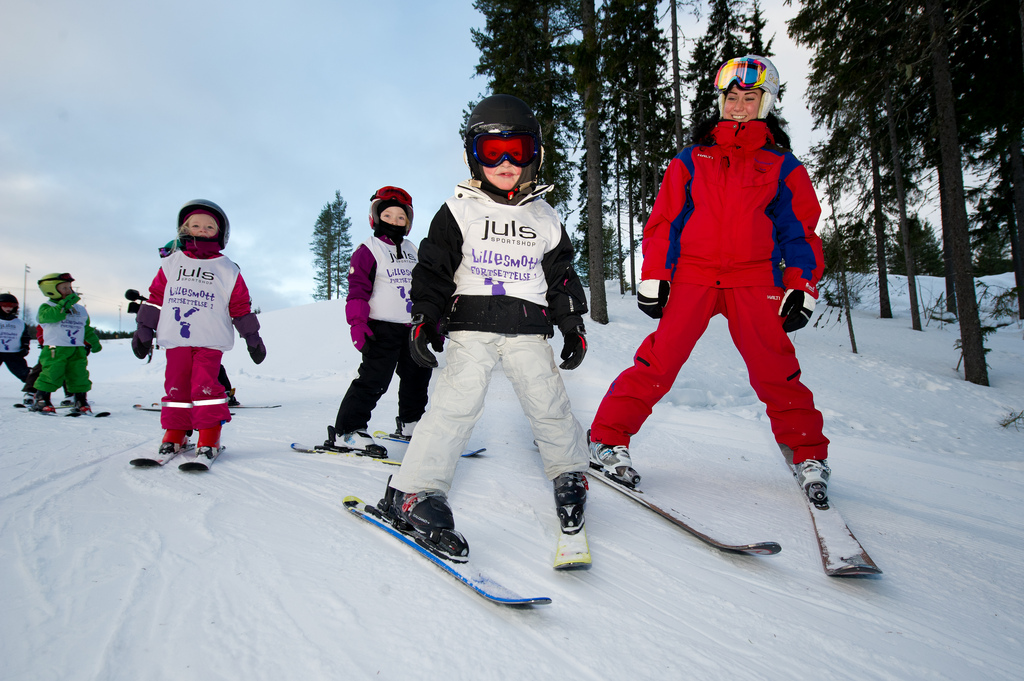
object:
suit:
[32, 296, 103, 396]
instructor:
[588, 54, 884, 580]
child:
[124, 200, 266, 472]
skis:
[129, 443, 227, 470]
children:
[339, 96, 589, 605]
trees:
[310, 0, 1024, 387]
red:
[591, 120, 830, 464]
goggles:
[473, 130, 541, 168]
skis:
[584, 466, 883, 577]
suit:
[388, 183, 590, 494]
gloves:
[406, 315, 589, 369]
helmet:
[36, 272, 74, 298]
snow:
[0, 271, 1024, 681]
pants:
[161, 346, 232, 430]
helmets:
[369, 186, 415, 236]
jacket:
[343, 236, 419, 324]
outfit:
[27, 292, 110, 417]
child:
[27, 272, 110, 417]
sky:
[2, 0, 498, 333]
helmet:
[714, 54, 782, 118]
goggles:
[714, 57, 768, 91]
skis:
[343, 495, 593, 606]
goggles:
[377, 186, 413, 204]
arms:
[345, 243, 378, 350]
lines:
[493, 575, 1024, 680]